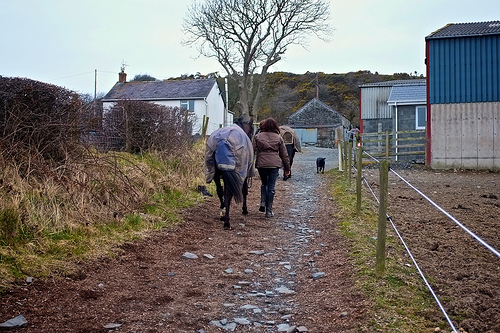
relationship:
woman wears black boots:
[251, 118, 289, 217] [267, 193, 275, 217]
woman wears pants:
[251, 118, 289, 217] [256, 168, 277, 218]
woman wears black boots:
[251, 118, 289, 217] [257, 182, 279, 221]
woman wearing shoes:
[254, 117, 289, 217] [257, 204, 274, 216]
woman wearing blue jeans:
[251, 118, 289, 217] [259, 169, 280, 193]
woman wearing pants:
[251, 118, 289, 217] [255, 168, 282, 220]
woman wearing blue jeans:
[251, 118, 289, 217] [249, 164, 280, 224]